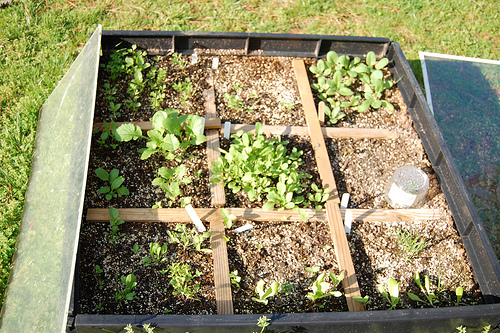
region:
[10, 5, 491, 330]
These are plants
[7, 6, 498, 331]
This is a farm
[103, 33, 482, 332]
Plants are growing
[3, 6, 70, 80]
Grass is short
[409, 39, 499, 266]
Window on the side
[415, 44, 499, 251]
Window is clear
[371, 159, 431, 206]
A container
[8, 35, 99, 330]
Lid on the side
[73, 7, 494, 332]
Black box for the container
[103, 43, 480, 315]
Boxes for sections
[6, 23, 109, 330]
screen frame for cold box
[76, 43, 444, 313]
wood dividers in cold box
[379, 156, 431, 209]
perforated plastic tub in garden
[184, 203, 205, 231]
white garden label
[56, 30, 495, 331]
black plastic cold frame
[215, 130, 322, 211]
vegetation in center of garden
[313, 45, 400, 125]
vegetation grown in top right corner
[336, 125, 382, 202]
patch of black potting soil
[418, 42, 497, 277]
fallen wire frame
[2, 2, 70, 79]
patch of grass behind cold frame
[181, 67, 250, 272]
the bar is wooden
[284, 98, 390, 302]
the bar is wooden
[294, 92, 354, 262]
the bar is wooden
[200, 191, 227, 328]
the bar is wooden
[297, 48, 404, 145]
plants in a big box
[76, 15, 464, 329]
plants in a big box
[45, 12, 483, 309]
This is a nursery bed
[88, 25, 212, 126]
A portion of a nursery bed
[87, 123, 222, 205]
A portion of a nursery bed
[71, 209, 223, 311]
A portion of a nursery bed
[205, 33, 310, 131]
A portion of a nursery bed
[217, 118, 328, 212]
A portion of a nursery bed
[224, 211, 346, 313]
A portion of a nursery bed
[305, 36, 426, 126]
A portion of a nursery bed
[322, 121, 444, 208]
A portion of a nursery bed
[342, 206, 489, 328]
A portion of a nursery bed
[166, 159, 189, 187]
plant in a container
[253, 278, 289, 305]
plant in a container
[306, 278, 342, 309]
plant in a container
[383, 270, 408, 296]
plant in a container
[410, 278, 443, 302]
plant in a container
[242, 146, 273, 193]
plant in a container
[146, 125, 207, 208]
plant in a container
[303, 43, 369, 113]
plant in a container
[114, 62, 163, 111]
plant in a container